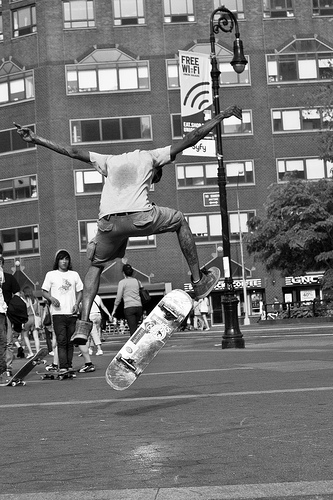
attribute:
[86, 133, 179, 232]
shirt — gray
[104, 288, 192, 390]
skate board — white, painted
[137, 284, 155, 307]
purse — black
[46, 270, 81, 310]
tee shirt — white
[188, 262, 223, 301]
shoes — skate, high top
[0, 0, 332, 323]
building — brick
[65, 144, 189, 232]
shirt — white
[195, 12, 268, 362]
lamp post — black, iron